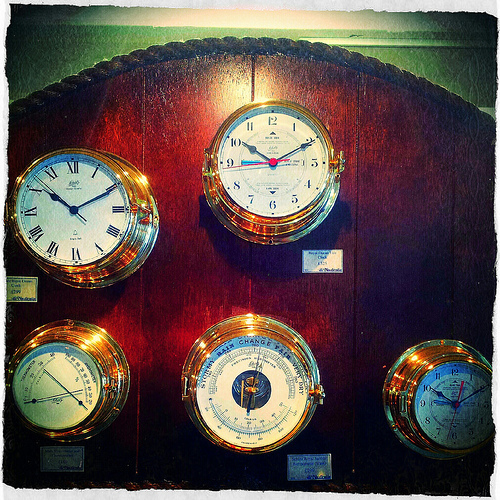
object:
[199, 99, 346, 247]
clock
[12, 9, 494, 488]
wall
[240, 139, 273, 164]
hand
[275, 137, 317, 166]
hand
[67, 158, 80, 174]
roman numeral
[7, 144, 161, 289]
clock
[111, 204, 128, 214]
roman numeral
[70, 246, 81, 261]
roman numeral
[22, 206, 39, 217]
roman numeral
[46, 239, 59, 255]
roman numeral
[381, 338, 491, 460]
clock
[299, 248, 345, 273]
card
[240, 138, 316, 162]
time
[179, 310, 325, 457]
barometer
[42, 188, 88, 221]
hour hand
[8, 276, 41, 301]
sign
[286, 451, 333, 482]
card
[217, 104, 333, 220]
glass face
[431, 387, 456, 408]
hand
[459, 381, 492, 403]
hand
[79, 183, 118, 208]
minute hand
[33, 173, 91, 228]
second hand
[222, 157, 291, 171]
second hand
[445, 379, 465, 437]
second hand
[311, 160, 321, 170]
number 3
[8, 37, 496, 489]
wood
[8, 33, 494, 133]
rope edge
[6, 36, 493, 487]
panel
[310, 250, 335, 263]
words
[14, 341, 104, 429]
gauge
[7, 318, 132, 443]
frame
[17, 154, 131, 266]
face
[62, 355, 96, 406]
arch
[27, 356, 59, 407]
arch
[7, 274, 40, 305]
border